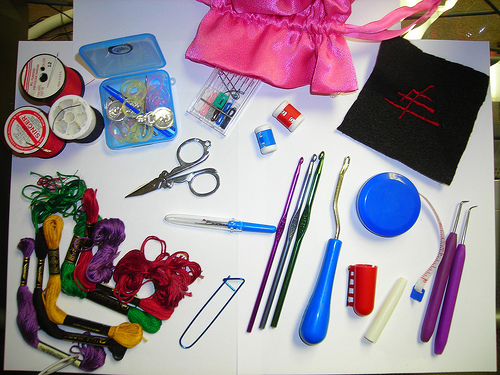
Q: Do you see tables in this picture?
A: Yes, there is a table.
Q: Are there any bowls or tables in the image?
A: Yes, there is a table.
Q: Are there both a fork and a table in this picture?
A: No, there is a table but no forks.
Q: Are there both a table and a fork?
A: No, there is a table but no forks.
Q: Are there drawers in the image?
A: No, there are no drawers.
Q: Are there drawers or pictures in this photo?
A: No, there are no drawers or pictures.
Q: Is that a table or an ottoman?
A: That is a table.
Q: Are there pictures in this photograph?
A: No, there are no pictures.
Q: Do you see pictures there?
A: No, there are no pictures.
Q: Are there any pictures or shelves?
A: No, there are no pictures or shelves.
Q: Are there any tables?
A: Yes, there is a table.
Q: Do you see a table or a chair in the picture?
A: Yes, there is a table.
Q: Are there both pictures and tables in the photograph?
A: No, there is a table but no pictures.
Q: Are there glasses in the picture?
A: No, there are no glasses.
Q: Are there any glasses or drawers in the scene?
A: No, there are no glasses or drawers.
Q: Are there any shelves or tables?
A: Yes, there is a table.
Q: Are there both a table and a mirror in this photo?
A: No, there is a table but no mirrors.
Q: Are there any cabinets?
A: No, there are no cabinets.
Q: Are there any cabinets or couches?
A: No, there are no cabinets or couches.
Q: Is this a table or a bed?
A: This is a table.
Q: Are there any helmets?
A: No, there are no helmets.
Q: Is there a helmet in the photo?
A: No, there are no helmets.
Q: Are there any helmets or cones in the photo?
A: No, there are no helmets or cones.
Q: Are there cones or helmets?
A: No, there are no helmets or cones.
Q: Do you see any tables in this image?
A: Yes, there is a table.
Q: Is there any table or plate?
A: Yes, there is a table.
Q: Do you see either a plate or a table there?
A: Yes, there is a table.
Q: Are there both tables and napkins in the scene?
A: No, there is a table but no napkins.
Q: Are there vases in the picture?
A: No, there are no vases.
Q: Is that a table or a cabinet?
A: That is a table.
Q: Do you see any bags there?
A: Yes, there is a bag.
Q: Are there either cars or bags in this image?
A: Yes, there is a bag.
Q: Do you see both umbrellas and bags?
A: No, there is a bag but no umbrellas.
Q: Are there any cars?
A: No, there are no cars.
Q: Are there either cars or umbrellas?
A: No, there are no cars or umbrellas.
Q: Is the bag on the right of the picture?
A: Yes, the bag is on the right of the image.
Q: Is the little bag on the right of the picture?
A: Yes, the bag is on the right of the image.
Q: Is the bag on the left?
A: No, the bag is on the right of the image.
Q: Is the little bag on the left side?
A: No, the bag is on the right of the image.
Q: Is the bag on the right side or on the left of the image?
A: The bag is on the right of the image.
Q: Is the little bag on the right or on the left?
A: The bag is on the right of the image.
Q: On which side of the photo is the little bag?
A: The bag is on the right of the image.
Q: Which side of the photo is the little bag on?
A: The bag is on the right of the image.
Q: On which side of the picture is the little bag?
A: The bag is on the right of the image.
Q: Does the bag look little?
A: Yes, the bag is little.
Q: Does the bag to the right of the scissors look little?
A: Yes, the bag is little.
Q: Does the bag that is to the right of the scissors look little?
A: Yes, the bag is little.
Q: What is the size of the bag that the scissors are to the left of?
A: The bag is little.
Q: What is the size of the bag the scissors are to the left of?
A: The bag is little.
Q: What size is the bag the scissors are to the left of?
A: The bag is little.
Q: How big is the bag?
A: The bag is little.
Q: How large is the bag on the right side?
A: The bag is little.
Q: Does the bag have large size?
A: No, the bag is little.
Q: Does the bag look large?
A: No, the bag is little.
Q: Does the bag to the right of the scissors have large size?
A: No, the bag is little.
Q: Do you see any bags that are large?
A: No, there is a bag but it is little.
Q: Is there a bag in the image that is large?
A: No, there is a bag but it is little.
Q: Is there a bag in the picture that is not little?
A: No, there is a bag but it is little.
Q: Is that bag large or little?
A: The bag is little.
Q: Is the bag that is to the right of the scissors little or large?
A: The bag is little.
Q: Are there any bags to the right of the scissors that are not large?
A: Yes, there is a bag to the right of the scissors.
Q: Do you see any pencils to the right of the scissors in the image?
A: No, there is a bag to the right of the scissors.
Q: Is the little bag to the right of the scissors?
A: Yes, the bag is to the right of the scissors.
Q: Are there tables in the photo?
A: Yes, there is a table.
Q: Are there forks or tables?
A: Yes, there is a table.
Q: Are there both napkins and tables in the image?
A: No, there is a table but no napkins.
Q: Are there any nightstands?
A: No, there are no nightstands.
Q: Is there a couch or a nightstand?
A: No, there are no nightstands or couches.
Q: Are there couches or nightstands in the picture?
A: No, there are no nightstands or couches.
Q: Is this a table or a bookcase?
A: This is a table.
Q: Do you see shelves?
A: No, there are no shelves.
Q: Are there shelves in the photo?
A: No, there are no shelves.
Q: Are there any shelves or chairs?
A: No, there are no shelves or chairs.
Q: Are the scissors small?
A: Yes, the scissors are small.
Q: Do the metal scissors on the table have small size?
A: Yes, the scissors are small.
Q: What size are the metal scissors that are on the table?
A: The scissors are small.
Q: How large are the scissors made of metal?
A: The scissors are small.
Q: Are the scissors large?
A: No, the scissors are small.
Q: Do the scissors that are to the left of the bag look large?
A: No, the scissors are small.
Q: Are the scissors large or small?
A: The scissors are small.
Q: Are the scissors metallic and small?
A: Yes, the scissors are metallic and small.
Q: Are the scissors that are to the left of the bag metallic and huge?
A: No, the scissors are metallic but small.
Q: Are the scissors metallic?
A: Yes, the scissors are metallic.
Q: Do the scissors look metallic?
A: Yes, the scissors are metallic.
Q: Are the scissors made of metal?
A: Yes, the scissors are made of metal.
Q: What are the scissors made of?
A: The scissors are made of metal.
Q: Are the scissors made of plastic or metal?
A: The scissors are made of metal.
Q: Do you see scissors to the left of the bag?
A: Yes, there are scissors to the left of the bag.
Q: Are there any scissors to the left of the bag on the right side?
A: Yes, there are scissors to the left of the bag.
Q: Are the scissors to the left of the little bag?
A: Yes, the scissors are to the left of the bag.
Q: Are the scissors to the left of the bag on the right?
A: Yes, the scissors are to the left of the bag.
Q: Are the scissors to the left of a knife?
A: No, the scissors are to the left of the bag.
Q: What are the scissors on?
A: The scissors are on the table.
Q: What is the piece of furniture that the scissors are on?
A: The piece of furniture is a table.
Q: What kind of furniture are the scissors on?
A: The scissors are on the table.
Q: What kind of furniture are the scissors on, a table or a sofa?
A: The scissors are on a table.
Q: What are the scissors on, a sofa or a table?
A: The scissors are on a table.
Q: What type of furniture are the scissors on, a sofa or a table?
A: The scissors are on a table.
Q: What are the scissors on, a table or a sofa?
A: The scissors are on a table.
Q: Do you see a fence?
A: No, there are no fences.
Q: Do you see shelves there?
A: No, there are no shelves.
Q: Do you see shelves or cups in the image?
A: No, there are no shelves or cups.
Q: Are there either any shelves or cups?
A: No, there are no shelves or cups.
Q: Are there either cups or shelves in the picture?
A: No, there are no shelves or cups.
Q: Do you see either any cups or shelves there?
A: No, there are no shelves or cups.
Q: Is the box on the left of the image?
A: Yes, the box is on the left of the image.